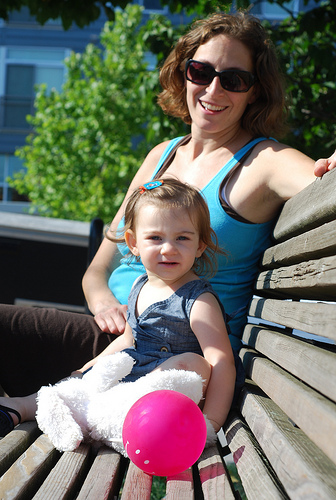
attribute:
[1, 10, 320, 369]
woman — adult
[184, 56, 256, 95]
glasses — black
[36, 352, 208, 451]
animal — white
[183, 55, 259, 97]
sunglasses — large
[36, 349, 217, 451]
stuffed animal — white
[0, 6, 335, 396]
woman — adult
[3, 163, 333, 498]
bench — wooden, brown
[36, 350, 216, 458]
animal — stuffed, fluffy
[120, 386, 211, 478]
balloon — red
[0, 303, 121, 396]
pants — black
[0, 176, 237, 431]
baby girl — little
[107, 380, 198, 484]
ball — pink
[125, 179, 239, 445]
toddler — sitting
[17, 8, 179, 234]
tree — distant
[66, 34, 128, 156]
tree — large, green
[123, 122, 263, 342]
top — blue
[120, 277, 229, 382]
jumper — blue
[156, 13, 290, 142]
hair — dark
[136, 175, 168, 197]
clip — orange, blue